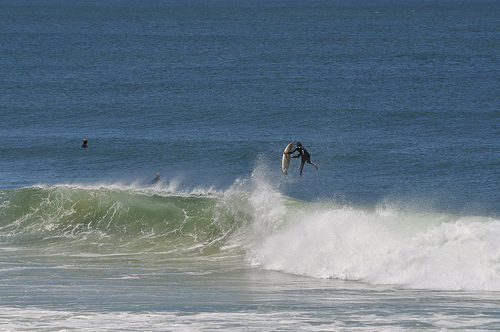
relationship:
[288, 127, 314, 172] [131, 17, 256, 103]
person in ocean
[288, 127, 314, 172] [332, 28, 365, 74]
person in sky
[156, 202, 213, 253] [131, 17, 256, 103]
foam on ocean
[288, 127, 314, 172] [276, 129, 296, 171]
person with surfboard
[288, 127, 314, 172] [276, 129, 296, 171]
person holding surfboard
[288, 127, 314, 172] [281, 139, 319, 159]
person wearing wetsuit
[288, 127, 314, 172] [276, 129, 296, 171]
person on surfboard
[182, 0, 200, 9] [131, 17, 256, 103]
water of ocean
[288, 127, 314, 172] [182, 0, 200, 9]
person in water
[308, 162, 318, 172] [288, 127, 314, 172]
foot of person